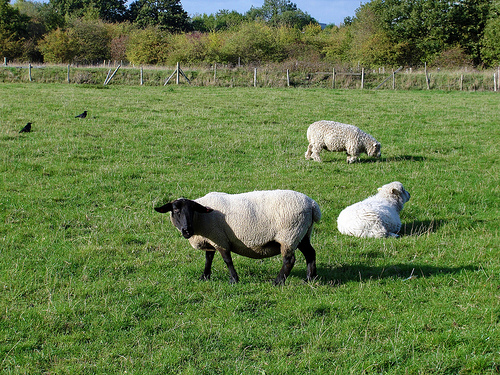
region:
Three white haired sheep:
[145, 98, 427, 305]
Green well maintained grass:
[42, 293, 318, 369]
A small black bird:
[14, 119, 41, 143]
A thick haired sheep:
[291, 113, 412, 176]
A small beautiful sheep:
[333, 174, 427, 259]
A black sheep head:
[155, 192, 217, 244]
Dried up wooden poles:
[250, 65, 499, 92]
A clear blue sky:
[319, 3, 348, 19]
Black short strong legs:
[192, 250, 335, 290]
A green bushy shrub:
[348, 9, 495, 77]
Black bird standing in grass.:
[66, 98, 101, 131]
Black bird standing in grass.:
[13, 108, 35, 145]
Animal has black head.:
[157, 195, 200, 237]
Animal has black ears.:
[148, 193, 227, 228]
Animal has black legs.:
[181, 259, 328, 295]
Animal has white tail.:
[301, 200, 326, 229]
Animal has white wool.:
[209, 184, 302, 249]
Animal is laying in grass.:
[339, 172, 419, 257]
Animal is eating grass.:
[294, 77, 394, 197]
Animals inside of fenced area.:
[121, 53, 446, 95]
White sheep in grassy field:
[293, 112, 394, 170]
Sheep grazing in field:
[292, 115, 398, 169]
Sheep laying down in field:
[330, 172, 423, 243]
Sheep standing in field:
[143, 173, 330, 288]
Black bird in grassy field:
[69, 106, 96, 126]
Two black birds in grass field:
[12, 103, 95, 147]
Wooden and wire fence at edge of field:
[5, 55, 499, 100]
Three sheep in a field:
[150, 114, 414, 289]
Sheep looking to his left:
[149, 195, 215, 245]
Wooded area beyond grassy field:
[100, 28, 325, 59]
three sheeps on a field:
[141, 110, 422, 295]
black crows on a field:
[11, 97, 92, 137]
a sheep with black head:
[150, 181, 325, 293]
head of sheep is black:
[151, 195, 206, 242]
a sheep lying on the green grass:
[330, 175, 420, 250]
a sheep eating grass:
[298, 107, 390, 169]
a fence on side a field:
[0, 55, 496, 100]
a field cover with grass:
[7, 81, 499, 373]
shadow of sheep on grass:
[168, 233, 488, 288]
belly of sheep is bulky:
[231, 225, 281, 265]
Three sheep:
[156, 115, 411, 295]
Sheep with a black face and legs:
[151, 187, 321, 283]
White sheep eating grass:
[306, 118, 379, 163]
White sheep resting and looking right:
[334, 180, 411, 240]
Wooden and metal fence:
[3, 56, 498, 92]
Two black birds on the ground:
[17, 107, 91, 134]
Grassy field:
[2, 81, 498, 373]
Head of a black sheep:
[156, 196, 208, 240]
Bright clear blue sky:
[180, 0, 360, 25]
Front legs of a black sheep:
[200, 250, 236, 280]